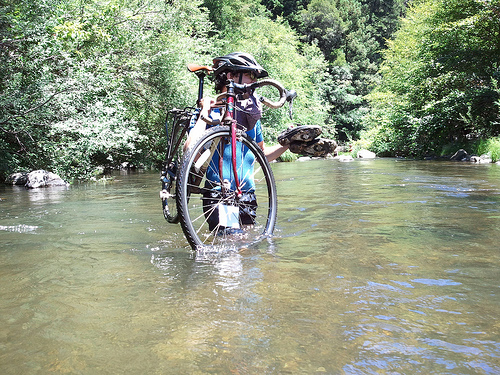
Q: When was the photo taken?
A: Daytime.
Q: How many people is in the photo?
A: One.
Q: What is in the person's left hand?
A: Shoes.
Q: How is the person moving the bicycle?
A: Carrying it.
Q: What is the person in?
A: Water.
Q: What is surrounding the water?
A: Trees.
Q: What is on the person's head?
A: Helmet.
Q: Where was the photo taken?
A: In a stream.